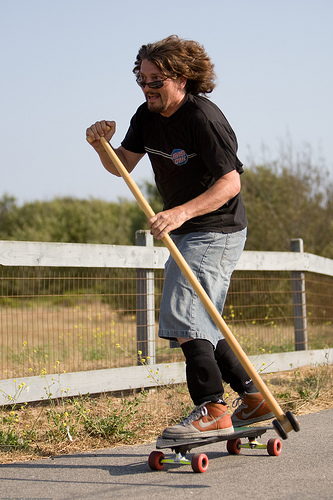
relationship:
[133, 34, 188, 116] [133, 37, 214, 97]
head has hair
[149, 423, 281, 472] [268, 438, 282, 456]
skateboard has wheel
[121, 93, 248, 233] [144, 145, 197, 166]
t-shirt has logo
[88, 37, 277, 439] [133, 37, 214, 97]
man has hair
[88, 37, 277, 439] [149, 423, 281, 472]
man riding skateboard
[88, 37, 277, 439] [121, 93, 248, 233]
man wering t-shirt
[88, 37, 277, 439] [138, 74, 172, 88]
man wering sunglasses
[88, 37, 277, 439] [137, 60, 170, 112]
man has face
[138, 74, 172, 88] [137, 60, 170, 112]
sunglasses are on face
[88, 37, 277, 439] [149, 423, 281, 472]
man standing on skateboard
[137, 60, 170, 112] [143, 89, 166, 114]
face has goatee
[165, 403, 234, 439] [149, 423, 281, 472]
shoe on top of skateboard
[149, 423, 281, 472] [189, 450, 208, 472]
skateboard has front wheel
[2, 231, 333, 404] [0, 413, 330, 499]
fence next to road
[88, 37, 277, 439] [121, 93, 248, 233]
man wearing t-shirt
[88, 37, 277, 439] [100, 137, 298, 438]
man holding mallet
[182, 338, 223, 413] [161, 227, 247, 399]
pads around leg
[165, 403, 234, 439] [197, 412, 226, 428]
shoe has logo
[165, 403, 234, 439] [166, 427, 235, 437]
shoe has sole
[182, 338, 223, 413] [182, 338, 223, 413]
pads are on pads